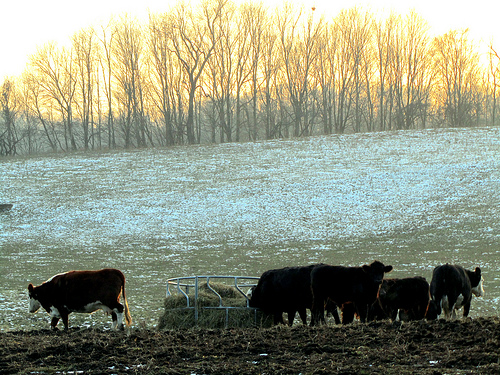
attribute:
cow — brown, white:
[23, 269, 134, 329]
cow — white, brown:
[20, 265, 139, 337]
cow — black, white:
[428, 263, 483, 320]